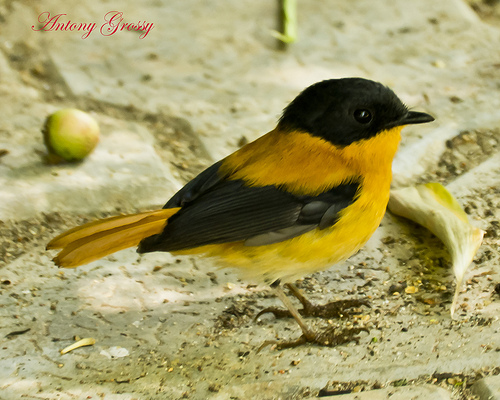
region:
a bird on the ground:
[19, 76, 426, 349]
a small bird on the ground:
[117, 76, 415, 289]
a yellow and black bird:
[89, 56, 367, 253]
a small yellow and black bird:
[121, 57, 443, 306]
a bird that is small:
[57, 54, 486, 310]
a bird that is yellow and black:
[114, 70, 493, 354]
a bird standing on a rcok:
[37, 6, 497, 361]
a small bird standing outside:
[78, 39, 498, 366]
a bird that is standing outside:
[61, 46, 469, 370]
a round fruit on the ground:
[42, 108, 102, 160]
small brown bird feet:
[250, 280, 372, 355]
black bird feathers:
[137, 153, 359, 265]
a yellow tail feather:
[46, 202, 175, 272]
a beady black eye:
[352, 102, 375, 127]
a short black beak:
[400, 103, 442, 129]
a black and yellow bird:
[37, 75, 434, 345]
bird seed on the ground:
[10, 118, 494, 398]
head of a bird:
[276, 64, 438, 140]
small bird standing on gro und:
[43, 71, 436, 348]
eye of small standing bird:
[351, 103, 380, 125]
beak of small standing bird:
[411, 103, 442, 138]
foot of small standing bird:
[278, 318, 374, 350]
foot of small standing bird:
[259, 293, 381, 321]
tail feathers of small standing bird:
[39, 208, 174, 276]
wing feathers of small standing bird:
[137, 167, 347, 260]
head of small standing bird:
[276, 71, 439, 151]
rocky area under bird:
[379, 268, 438, 340]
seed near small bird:
[30, 94, 114, 166]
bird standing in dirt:
[36, 61, 442, 354]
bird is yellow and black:
[48, 55, 445, 325]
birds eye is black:
[348, 106, 373, 133]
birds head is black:
[266, 76, 417, 149]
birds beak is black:
[388, 102, 434, 132]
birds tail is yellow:
[39, 189, 176, 283]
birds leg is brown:
[258, 267, 370, 365]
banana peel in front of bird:
[378, 164, 497, 324]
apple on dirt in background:
[30, 99, 101, 170]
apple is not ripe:
[31, 106, 103, 163]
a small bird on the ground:
[46, 46, 442, 381]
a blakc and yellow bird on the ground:
[97, 43, 474, 381]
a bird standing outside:
[87, 71, 489, 273]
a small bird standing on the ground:
[41, 11, 449, 376]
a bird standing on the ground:
[84, 7, 449, 327]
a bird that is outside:
[127, 14, 482, 297]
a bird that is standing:
[46, 6, 463, 353]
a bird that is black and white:
[64, 32, 493, 385]